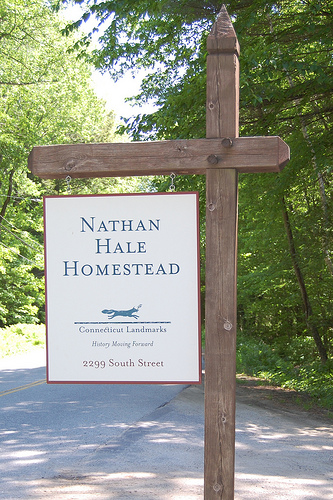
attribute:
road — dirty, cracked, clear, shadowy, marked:
[13, 338, 276, 499]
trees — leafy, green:
[0, 4, 326, 387]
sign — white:
[38, 193, 206, 388]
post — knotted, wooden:
[189, 5, 259, 499]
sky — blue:
[66, 7, 194, 129]